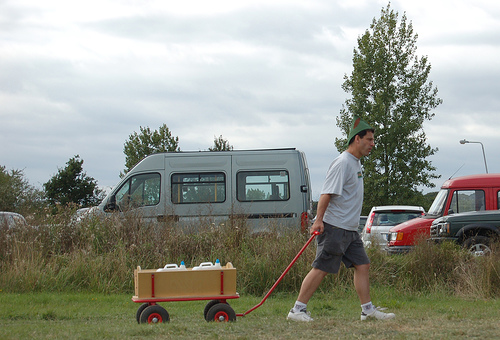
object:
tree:
[330, 3, 442, 212]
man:
[285, 120, 395, 323]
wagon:
[129, 262, 241, 324]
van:
[68, 147, 313, 242]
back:
[257, 147, 313, 245]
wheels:
[135, 300, 237, 326]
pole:
[240, 231, 320, 315]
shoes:
[286, 301, 395, 321]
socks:
[293, 300, 377, 311]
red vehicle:
[386, 172, 500, 256]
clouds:
[278, 33, 350, 80]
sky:
[0, 0, 499, 201]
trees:
[0, 127, 180, 211]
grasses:
[38, 229, 112, 290]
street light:
[459, 140, 489, 175]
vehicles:
[362, 174, 500, 266]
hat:
[341, 118, 376, 145]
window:
[234, 169, 289, 202]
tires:
[133, 301, 237, 325]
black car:
[428, 209, 499, 264]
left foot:
[357, 300, 395, 321]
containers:
[147, 255, 257, 266]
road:
[76, 318, 120, 338]